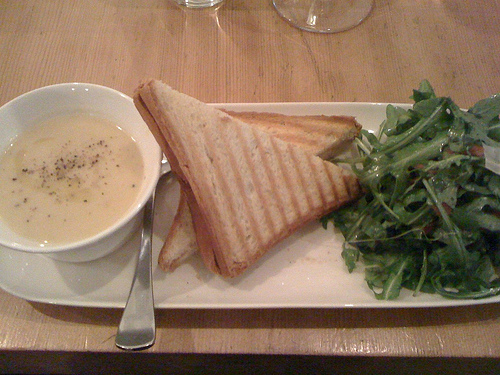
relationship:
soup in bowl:
[2, 115, 145, 242] [1, 79, 165, 262]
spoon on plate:
[114, 154, 172, 351] [1, 100, 499, 310]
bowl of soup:
[1, 79, 165, 262] [2, 115, 145, 242]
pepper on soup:
[9, 134, 137, 221] [2, 115, 145, 242]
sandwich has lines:
[130, 75, 361, 279] [188, 114, 354, 260]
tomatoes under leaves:
[415, 143, 486, 215] [327, 76, 499, 303]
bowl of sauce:
[1, 79, 165, 262] [2, 115, 145, 242]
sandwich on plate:
[130, 75, 361, 279] [1, 100, 499, 310]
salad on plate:
[322, 77, 500, 300] [1, 100, 499, 310]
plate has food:
[1, 100, 499, 310] [1, 77, 499, 301]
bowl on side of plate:
[1, 79, 165, 262] [1, 100, 499, 310]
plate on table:
[1, 100, 499, 310] [1, 1, 499, 358]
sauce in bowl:
[2, 115, 145, 242] [1, 79, 165, 262]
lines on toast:
[188, 114, 354, 260] [130, 75, 361, 279]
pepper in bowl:
[9, 134, 137, 221] [1, 79, 165, 262]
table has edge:
[1, 1, 499, 358] [2, 348, 500, 374]